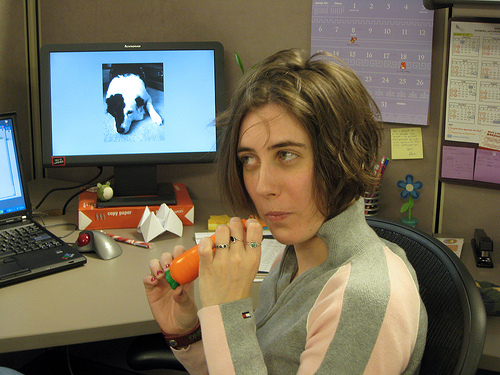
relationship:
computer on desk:
[0, 112, 86, 289] [2, 178, 499, 369]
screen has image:
[40, 40, 222, 164] [101, 62, 165, 139]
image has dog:
[101, 62, 165, 139] [108, 64, 164, 134]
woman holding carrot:
[140, 45, 430, 373] [160, 218, 266, 289]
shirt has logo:
[170, 200, 429, 374] [239, 309, 255, 320]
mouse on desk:
[73, 227, 126, 263] [2, 178, 499, 369]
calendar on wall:
[306, 1, 435, 125] [1, 2, 499, 243]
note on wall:
[390, 125, 427, 164] [1, 2, 499, 243]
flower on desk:
[394, 172, 426, 225] [2, 178, 499, 369]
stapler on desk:
[471, 225, 497, 270] [2, 178, 499, 369]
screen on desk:
[40, 40, 222, 164] [2, 178, 499, 369]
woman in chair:
[140, 45, 430, 373] [366, 214, 491, 374]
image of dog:
[101, 62, 165, 139] [108, 64, 164, 134]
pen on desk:
[101, 226, 152, 254] [2, 178, 499, 369]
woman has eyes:
[140, 45, 430, 373] [238, 150, 300, 166]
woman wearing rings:
[140, 45, 430, 373] [209, 234, 261, 253]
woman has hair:
[140, 45, 430, 373] [210, 48, 385, 219]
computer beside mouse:
[0, 112, 86, 289] [73, 227, 126, 263]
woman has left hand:
[140, 45, 430, 373] [196, 214, 267, 305]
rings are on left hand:
[209, 234, 261, 253] [196, 214, 267, 305]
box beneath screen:
[77, 182, 195, 230] [40, 40, 222, 164]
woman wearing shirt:
[140, 45, 430, 373] [170, 200, 429, 374]